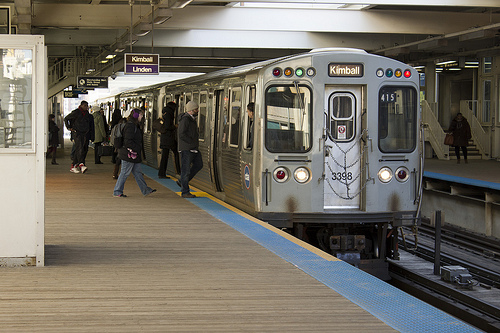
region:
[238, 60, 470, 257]
a train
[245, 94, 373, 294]
a train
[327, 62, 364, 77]
the trains route line name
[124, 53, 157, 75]
information sign attached to the ceiling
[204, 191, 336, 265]
yellow no crossing safety line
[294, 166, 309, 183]
the trains front headlights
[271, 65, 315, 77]
the in service lights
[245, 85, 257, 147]
the train engineers side window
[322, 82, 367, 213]
the train cars access doors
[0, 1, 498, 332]
a passenger commuter train station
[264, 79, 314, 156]
the trains front windshield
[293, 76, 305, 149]
the trains front windshield wiper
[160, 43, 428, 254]
a silver train passenger car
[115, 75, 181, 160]
a silver train passenger car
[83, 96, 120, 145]
a silver train passenger car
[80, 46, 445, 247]
a commuter train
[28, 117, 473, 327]
a train boarding platform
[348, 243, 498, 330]
a set of train tracks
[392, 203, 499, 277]
a set of train tracks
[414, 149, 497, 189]
a train passenger boarding platform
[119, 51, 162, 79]
a passenger information sign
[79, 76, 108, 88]
a passenger information sign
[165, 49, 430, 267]
large mass transit rail train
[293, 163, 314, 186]
transit rail train head light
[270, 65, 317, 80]
colored signal train lights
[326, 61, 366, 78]
mass transit rail line name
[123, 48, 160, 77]
mass transit location signs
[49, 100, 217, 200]
mass transit rail passengers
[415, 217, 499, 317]
mass transit rail train tracks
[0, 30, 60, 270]
mass transit rail ticket booth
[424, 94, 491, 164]
passenger walking off of stairs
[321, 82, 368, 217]
passenger train car door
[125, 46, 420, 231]
train parked in station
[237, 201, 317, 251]
yellow line on platform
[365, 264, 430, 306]
blue edge on side of platform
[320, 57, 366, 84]
white word on train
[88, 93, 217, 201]
people walking toward train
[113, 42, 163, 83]
signs suspended from ceiling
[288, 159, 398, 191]
lights on front of train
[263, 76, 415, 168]
two windows on train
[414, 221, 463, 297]
rails in between platforms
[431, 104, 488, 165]
stairwell inside of train station